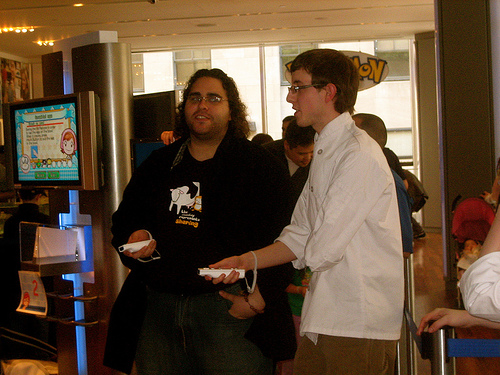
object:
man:
[257, 119, 317, 219]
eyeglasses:
[187, 95, 229, 103]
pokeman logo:
[281, 48, 386, 85]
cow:
[168, 181, 200, 215]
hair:
[172, 67, 249, 140]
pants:
[295, 334, 398, 374]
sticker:
[280, 50, 389, 92]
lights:
[0, 24, 35, 33]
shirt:
[158, 138, 215, 276]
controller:
[119, 239, 155, 253]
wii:
[34, 227, 79, 257]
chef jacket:
[274, 110, 403, 344]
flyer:
[15, 271, 48, 317]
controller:
[197, 268, 246, 279]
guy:
[102, 68, 297, 375]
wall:
[433, 0, 493, 203]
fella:
[205, 49, 406, 375]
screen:
[15, 103, 79, 181]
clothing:
[101, 128, 298, 375]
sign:
[280, 50, 390, 91]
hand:
[124, 229, 157, 259]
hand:
[204, 255, 249, 284]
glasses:
[287, 84, 318, 93]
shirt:
[272, 111, 405, 346]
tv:
[14, 103, 79, 181]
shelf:
[0, 293, 105, 356]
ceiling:
[1, 0, 435, 39]